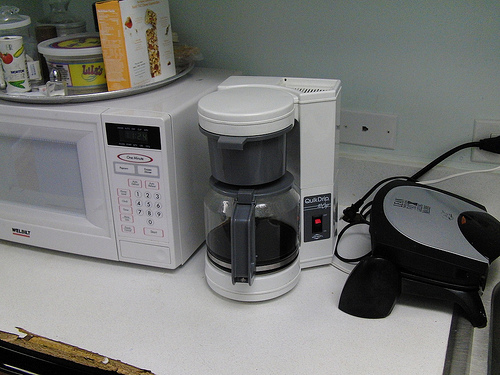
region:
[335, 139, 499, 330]
mostly black George Foreman grill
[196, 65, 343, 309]
mostly white simple coffee maker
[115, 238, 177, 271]
button to open a microwave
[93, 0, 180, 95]
back and side of a box of granola bars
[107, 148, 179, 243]
flat microwave buttons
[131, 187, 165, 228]
microwave number buttons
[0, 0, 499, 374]
kitchen area with several appliances and a tray of food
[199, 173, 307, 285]
empty coffee pot with a black handle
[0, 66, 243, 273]
mostly white microwave with a blank digital display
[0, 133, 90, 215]
window on a microwave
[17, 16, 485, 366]
Appliances on a kitchen counter.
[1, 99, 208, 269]
A white microwave.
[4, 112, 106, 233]
The door on a microwave.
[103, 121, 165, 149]
Display panel on a microwave.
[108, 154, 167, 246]
The controls on a microwave.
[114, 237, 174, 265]
The handle to open a microwave door.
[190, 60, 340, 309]
An electric coffee pot.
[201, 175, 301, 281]
The carafe of the coffee pot.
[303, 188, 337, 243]
The controls for the coffee pot.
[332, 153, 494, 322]
A black and silver kitchen appliance.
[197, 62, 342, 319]
White coffee pot on counter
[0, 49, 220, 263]
White microwave on couinter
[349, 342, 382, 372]
Part of white counter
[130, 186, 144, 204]
Black and white button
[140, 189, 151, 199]
Black and white button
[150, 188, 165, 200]
Black and white button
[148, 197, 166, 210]
Black and white button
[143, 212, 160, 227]
Black and white button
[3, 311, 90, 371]
Small crack on the counter top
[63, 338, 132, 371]
Small crack on the counter top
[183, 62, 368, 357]
coffemaker on the counter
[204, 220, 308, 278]
the coffee is black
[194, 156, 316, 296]
the coffee is black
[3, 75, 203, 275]
a white microwave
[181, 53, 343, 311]
a white coffee maker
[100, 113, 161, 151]
screen of microwave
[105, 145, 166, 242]
control panel of microwave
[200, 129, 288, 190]
black filter basket of coffee maker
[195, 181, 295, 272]
carafe of coffee maker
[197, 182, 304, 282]
a carafe of glass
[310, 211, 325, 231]
on-off switch of coffee maker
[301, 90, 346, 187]
reservoir behind carafe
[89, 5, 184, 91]
a box of cereal